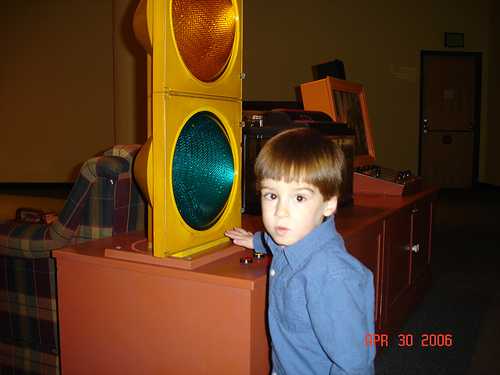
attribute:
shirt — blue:
[253, 216, 377, 374]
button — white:
[267, 267, 278, 280]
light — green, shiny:
[169, 105, 235, 233]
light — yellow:
[172, 2, 240, 85]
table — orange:
[50, 182, 441, 375]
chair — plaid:
[3, 141, 147, 375]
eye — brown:
[293, 192, 309, 203]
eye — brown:
[266, 191, 278, 202]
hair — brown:
[254, 129, 344, 202]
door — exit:
[419, 51, 482, 188]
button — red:
[237, 255, 255, 266]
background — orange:
[3, 1, 500, 188]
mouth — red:
[272, 223, 294, 235]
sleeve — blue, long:
[303, 273, 374, 375]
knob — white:
[412, 244, 421, 255]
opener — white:
[410, 242, 422, 258]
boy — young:
[222, 126, 377, 373]